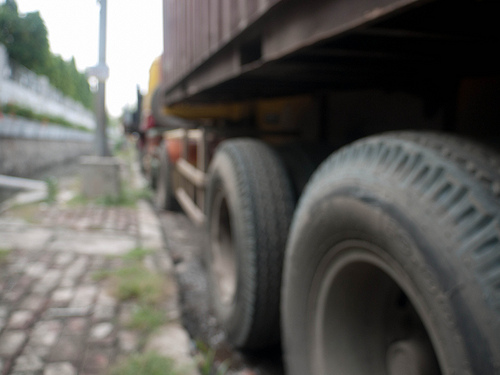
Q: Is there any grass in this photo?
A: Yes, there is grass.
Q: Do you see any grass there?
A: Yes, there is grass.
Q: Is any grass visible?
A: Yes, there is grass.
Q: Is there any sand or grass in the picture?
A: Yes, there is grass.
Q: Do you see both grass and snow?
A: No, there is grass but no snow.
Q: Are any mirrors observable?
A: No, there are no mirrors.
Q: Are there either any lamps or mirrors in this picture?
A: No, there are no mirrors or lamps.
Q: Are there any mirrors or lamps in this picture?
A: No, there are no mirrors or lamps.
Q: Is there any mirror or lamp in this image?
A: No, there are no mirrors or lamps.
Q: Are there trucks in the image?
A: Yes, there is a truck.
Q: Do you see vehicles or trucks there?
A: Yes, there is a truck.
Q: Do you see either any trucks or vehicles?
A: Yes, there is a truck.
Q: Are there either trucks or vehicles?
A: Yes, there is a truck.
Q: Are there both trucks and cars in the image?
A: No, there is a truck but no cars.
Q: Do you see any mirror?
A: No, there are no mirrors.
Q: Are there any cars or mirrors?
A: No, there are no mirrors or cars.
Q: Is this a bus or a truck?
A: This is a truck.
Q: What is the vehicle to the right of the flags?
A: The vehicle is a truck.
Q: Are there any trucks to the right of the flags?
A: Yes, there is a truck to the right of the flags.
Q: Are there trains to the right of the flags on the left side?
A: No, there is a truck to the right of the flags.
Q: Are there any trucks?
A: Yes, there is a truck.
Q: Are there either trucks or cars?
A: Yes, there is a truck.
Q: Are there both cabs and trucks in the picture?
A: No, there is a truck but no taxis.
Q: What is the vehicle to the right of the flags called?
A: The vehicle is a truck.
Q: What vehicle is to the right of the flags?
A: The vehicle is a truck.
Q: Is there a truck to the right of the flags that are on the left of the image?
A: Yes, there is a truck to the right of the flags.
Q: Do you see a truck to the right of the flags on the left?
A: Yes, there is a truck to the right of the flags.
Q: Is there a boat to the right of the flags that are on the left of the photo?
A: No, there is a truck to the right of the flags.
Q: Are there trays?
A: No, there are no trays.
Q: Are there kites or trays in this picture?
A: No, there are no trays or kites.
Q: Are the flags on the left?
A: Yes, the flags are on the left of the image.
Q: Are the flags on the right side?
A: No, the flags are on the left of the image.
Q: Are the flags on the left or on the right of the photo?
A: The flags are on the left of the image.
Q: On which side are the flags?
A: The flags are on the left of the image.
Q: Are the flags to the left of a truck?
A: Yes, the flags are to the left of a truck.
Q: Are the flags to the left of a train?
A: No, the flags are to the left of a truck.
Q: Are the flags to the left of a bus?
A: No, the flags are to the left of the truck.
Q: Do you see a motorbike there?
A: No, there are no motorcycles.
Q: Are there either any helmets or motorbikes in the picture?
A: No, there are no motorbikes or helmets.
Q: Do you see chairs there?
A: No, there are no chairs.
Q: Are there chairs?
A: No, there are no chairs.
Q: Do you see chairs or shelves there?
A: No, there are no chairs or shelves.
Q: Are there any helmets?
A: No, there are no helmets.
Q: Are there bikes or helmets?
A: No, there are no helmets or bikes.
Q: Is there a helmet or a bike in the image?
A: No, there are no helmets or bikes.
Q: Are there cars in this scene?
A: No, there are no cars.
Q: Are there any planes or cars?
A: No, there are no cars or planes.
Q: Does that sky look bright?
A: Yes, the sky is bright.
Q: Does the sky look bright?
A: Yes, the sky is bright.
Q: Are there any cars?
A: No, there are no cars.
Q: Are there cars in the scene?
A: No, there are no cars.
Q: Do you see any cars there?
A: No, there are no cars.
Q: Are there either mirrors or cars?
A: No, there are no cars or mirrors.